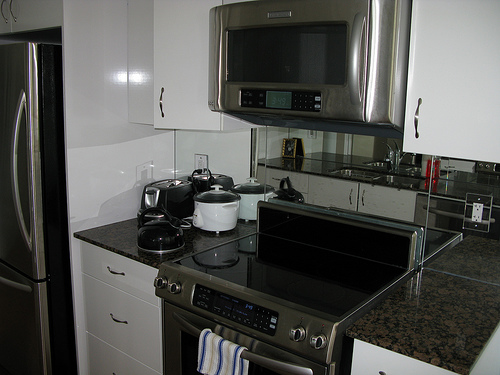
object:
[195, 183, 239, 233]
crock pot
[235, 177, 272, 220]
crock pot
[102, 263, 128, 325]
pulls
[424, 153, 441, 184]
soap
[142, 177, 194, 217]
oven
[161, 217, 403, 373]
oven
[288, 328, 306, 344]
knob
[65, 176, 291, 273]
counter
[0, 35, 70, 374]
refrigerator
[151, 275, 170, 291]
knobs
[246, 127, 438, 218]
mirrored wall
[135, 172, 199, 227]
toaster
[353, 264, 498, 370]
counter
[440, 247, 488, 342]
kite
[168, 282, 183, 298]
knob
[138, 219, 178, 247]
pot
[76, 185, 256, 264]
counter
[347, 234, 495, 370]
countertop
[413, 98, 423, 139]
handle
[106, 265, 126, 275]
handle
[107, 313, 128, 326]
handle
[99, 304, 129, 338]
handle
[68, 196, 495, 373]
cabinet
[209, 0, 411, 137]
microwave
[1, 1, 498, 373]
kitchen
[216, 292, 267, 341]
clock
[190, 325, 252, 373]
towel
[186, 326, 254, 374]
dishtowel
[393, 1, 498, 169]
cabinet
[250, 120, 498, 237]
mirror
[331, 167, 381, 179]
sink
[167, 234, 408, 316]
stove top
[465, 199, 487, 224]
outlet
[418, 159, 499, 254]
wall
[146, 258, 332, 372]
oven door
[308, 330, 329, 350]
knob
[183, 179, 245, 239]
cooker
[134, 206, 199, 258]
tea kettle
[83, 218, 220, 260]
counter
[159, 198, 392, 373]
stove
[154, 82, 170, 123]
handle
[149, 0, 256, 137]
cabinet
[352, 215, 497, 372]
counter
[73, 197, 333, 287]
counter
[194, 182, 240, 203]
lid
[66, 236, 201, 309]
cabinet